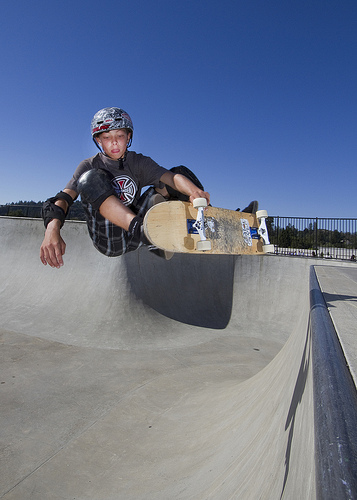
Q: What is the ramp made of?
A: Concrete.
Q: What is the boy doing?
A: Skateboarding.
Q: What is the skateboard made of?
A: Wood.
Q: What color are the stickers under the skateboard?
A: Blue and white.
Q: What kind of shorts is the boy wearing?
A: Plaid.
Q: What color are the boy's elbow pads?
A: Black.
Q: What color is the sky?
A: Blue.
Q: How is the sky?
A: Sunny and clear.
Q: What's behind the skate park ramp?
A: A fence.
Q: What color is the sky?
A: Blue.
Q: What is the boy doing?
A: Skateboarding.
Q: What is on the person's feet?
A: Skateboard.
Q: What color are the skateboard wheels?
A: White.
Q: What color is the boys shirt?
A: Gray.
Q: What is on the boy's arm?
A: Elbow padding?.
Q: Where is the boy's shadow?
A: Right side.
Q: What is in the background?
A: Trees.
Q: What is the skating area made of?
A: Concrete.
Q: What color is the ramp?
A: White.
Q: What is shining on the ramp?
A: Sun.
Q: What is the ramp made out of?
A: Concrete.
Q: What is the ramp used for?
A: Skateboarding.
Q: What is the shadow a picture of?
A: Skateboarder.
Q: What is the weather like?
A: Sunny.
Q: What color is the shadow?
A: Gray.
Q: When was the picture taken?
A: Daytime.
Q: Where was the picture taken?
A: At a skatepark.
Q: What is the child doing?
A: Skateboarding.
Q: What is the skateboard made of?
A: Wood.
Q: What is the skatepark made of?
A: Cement.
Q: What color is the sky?
A: Blue.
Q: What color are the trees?
A: Green.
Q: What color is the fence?
A: Black.